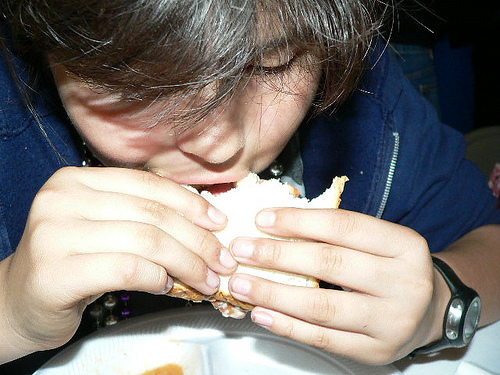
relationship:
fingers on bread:
[87, 170, 376, 347] [177, 167, 341, 308]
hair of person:
[3, 2, 399, 115] [3, 4, 499, 368]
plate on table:
[33, 303, 397, 373] [2, 254, 494, 372]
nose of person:
[168, 114, 249, 162] [3, 4, 499, 368]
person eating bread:
[3, 4, 499, 368] [177, 167, 341, 308]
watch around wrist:
[424, 238, 478, 356] [424, 242, 482, 354]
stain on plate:
[137, 353, 177, 375] [33, 303, 397, 373]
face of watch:
[464, 303, 479, 340] [424, 238, 478, 356]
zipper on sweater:
[356, 128, 412, 220] [2, 32, 494, 322]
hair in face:
[3, 2, 399, 115] [464, 303, 479, 340]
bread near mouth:
[177, 167, 341, 308] [173, 164, 244, 199]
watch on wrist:
[424, 238, 478, 356] [424, 242, 482, 354]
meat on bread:
[268, 166, 300, 206] [177, 167, 341, 308]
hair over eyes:
[3, 2, 399, 115] [89, 41, 287, 74]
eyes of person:
[89, 41, 287, 74] [3, 4, 499, 368]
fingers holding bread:
[87, 170, 376, 347] [177, 167, 341, 308]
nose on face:
[168, 114, 249, 162] [47, 18, 329, 195]